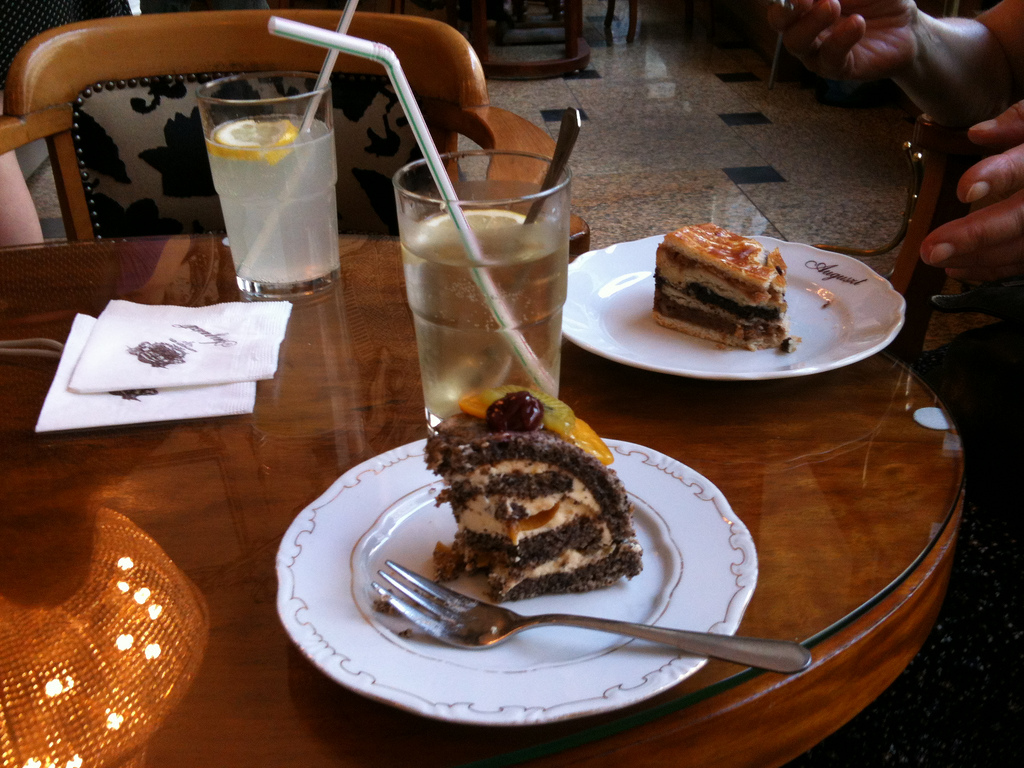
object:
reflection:
[0, 492, 213, 763]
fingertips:
[918, 96, 1020, 285]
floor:
[0, 0, 1024, 349]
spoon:
[452, 100, 583, 414]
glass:
[393, 150, 571, 441]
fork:
[364, 559, 810, 689]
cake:
[425, 380, 638, 604]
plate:
[268, 408, 767, 734]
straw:
[517, 86, 586, 222]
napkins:
[33, 297, 293, 442]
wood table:
[5, 232, 964, 768]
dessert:
[428, 384, 638, 604]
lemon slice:
[210, 108, 297, 167]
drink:
[195, 82, 338, 302]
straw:
[268, 1, 561, 425]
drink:
[392, 150, 572, 451]